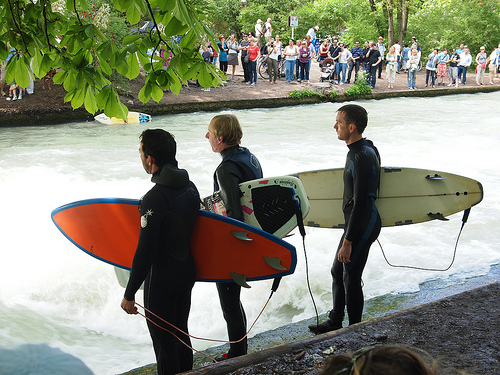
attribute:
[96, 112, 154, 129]
surf board — floating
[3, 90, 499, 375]
water — rushing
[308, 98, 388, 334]
surfer — standing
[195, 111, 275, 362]
surfer — standing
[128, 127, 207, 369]
surfer — standing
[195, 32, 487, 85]
spectators — recording, watching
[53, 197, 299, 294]
surf board — red, blue, orange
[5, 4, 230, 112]
branches — hanging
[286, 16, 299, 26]
sign — white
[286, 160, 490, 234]
surf board — white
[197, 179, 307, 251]
surf board — white, pink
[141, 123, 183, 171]
hair — black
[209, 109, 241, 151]
hair — blond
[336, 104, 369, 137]
hair — grey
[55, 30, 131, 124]
leaves — green, hanging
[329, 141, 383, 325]
wetsuit — black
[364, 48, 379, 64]
shirt — black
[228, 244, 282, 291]
fins — grey